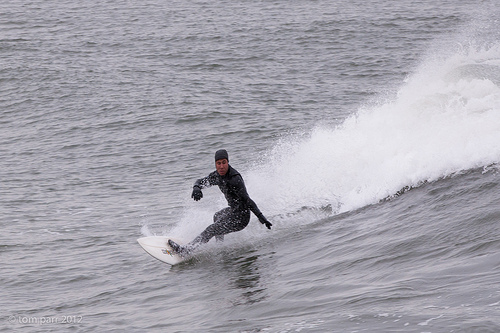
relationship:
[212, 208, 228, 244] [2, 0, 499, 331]
leg in ocean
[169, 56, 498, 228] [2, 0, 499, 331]
wave in ocean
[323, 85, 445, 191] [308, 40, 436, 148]
waves in gray ocean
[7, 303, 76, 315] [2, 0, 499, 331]
wave in ocean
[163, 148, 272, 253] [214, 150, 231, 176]
man has head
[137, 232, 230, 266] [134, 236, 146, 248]
board has tip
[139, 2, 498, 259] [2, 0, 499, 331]
wave in ocean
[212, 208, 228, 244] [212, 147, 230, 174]
leg has head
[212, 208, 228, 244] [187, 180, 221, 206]
leg has left hand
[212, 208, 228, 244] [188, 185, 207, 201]
leg has right hand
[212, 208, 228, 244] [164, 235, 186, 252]
leg has foot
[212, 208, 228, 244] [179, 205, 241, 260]
leg has leg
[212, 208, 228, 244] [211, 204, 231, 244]
leg has leg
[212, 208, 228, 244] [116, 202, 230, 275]
leg has board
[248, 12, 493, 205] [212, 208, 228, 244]
water behind leg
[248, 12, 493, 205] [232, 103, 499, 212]
water sprayed in wake